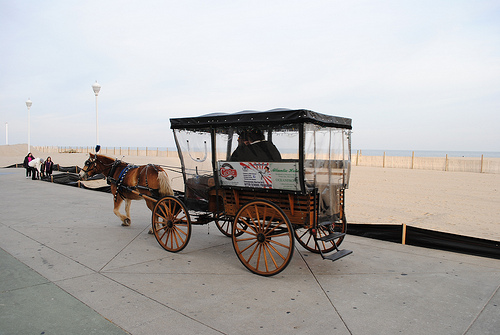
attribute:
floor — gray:
[4, 168, 499, 334]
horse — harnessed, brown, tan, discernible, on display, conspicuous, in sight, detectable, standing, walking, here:
[79, 154, 175, 235]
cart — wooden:
[170, 109, 346, 226]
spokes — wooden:
[236, 201, 291, 274]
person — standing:
[44, 154, 54, 182]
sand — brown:
[4, 142, 499, 244]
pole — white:
[93, 91, 99, 159]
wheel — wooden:
[234, 203, 292, 276]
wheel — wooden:
[154, 198, 190, 251]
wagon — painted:
[150, 107, 353, 280]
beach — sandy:
[2, 143, 499, 243]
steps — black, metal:
[314, 213, 352, 263]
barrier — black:
[8, 161, 499, 258]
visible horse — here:
[79, 153, 175, 235]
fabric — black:
[8, 159, 499, 263]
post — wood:
[400, 221, 407, 245]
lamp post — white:
[94, 95, 100, 157]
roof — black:
[170, 105, 353, 128]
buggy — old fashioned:
[149, 102, 350, 278]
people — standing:
[23, 154, 53, 181]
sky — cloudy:
[4, 1, 498, 149]